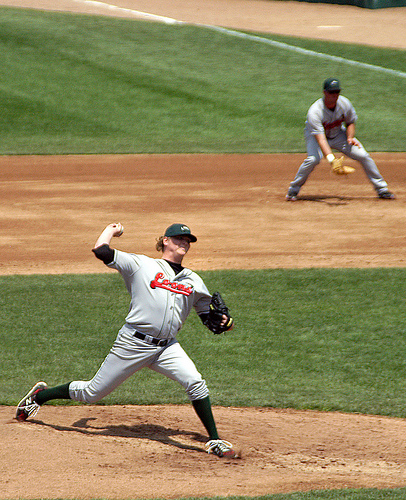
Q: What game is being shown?
A: Baseball.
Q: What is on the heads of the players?
A: Caps.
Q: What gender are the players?
A: Male.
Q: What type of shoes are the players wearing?
A: Sneakers.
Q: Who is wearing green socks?
A: The closest player.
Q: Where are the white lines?
A: On the ground.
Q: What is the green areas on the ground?
A: Grass.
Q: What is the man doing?
A: Throwing a ball.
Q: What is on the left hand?
A: A black ball glove.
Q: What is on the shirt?
A: Red writing.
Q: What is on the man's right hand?
A: A ball glove.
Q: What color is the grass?
A: Green.